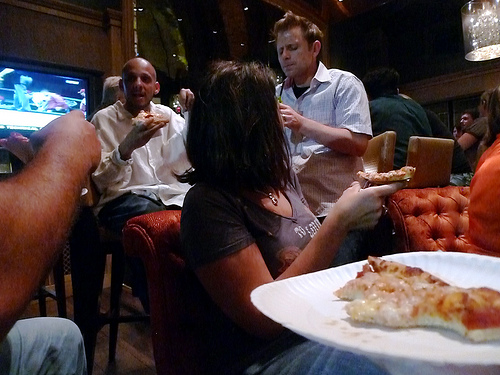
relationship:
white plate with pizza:
[241, 243, 496, 368] [336, 250, 498, 346]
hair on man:
[275, 10, 325, 45] [258, 4, 380, 255]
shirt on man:
[88, 97, 195, 206] [67, 55, 195, 373]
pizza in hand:
[355, 164, 418, 185] [332, 179, 407, 238]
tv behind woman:
[2, 60, 109, 154] [169, 57, 410, 373]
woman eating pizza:
[169, 57, 410, 373] [335, 254, 499, 342]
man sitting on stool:
[67, 55, 195, 373] [90, 231, 150, 373]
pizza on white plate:
[348, 263, 488, 331] [249, 250, 499, 368]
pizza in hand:
[355, 164, 418, 185] [334, 181, 403, 232]